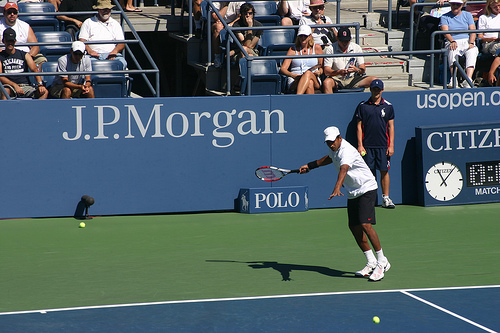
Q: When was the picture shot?
A: Daytime.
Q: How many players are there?
A: 1.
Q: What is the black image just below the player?
A: A shadow.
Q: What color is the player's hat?
A: White.